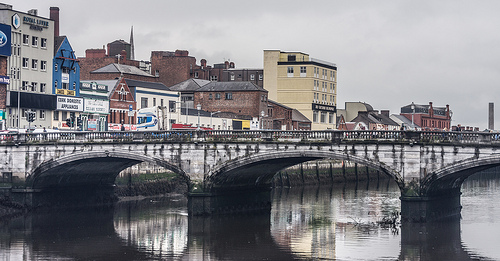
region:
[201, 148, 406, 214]
a stone archway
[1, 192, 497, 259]
part of a reflective river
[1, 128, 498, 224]
a long stone white dirty bridge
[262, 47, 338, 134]
a tall building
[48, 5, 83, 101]
a blue building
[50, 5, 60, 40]
a red brick fire chimney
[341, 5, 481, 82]
a patch of grey sky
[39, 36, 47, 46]
a single window of a building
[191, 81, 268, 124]
a break building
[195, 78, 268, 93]
a black pointed roof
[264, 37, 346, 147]
a tall multi story building.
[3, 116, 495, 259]
A bridge spanning a river.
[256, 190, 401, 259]
A reflection of a city.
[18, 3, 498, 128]
A hazy cloud filled sky.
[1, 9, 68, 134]
a tall white building.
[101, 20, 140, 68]
A building in a city.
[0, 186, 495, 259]
A large body of water.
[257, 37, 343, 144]
a multi story building.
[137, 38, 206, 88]
a small red building.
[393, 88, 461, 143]
a two story building.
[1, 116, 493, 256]
a bridge over a river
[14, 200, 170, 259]
reflection of bridge on the water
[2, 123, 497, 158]
bridge is fenced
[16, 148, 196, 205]
arch on bridge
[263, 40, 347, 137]
a yellow building in front a river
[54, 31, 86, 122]
a blue building in front a river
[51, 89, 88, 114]
a sign in front a building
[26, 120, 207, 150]
people crossing the bridge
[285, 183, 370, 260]
reflection of building on the water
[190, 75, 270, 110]
black roof of building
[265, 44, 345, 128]
a brown building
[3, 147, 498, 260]
water under a bridge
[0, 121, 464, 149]
bridge with cars driving on it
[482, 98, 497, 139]
smoke stack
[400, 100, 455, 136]
red house up on hill with many windows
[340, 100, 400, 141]
house with two chimneys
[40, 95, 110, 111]
two advertising signs hanging on poles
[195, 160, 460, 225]
arch of a bridge with water below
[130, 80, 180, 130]
building with many windows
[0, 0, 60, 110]
white business building with windows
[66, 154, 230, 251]
water under the bridge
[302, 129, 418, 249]
water under the bridge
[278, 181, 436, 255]
water under the bridge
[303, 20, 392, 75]
the sky is overcast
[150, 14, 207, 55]
the sky is overcast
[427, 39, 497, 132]
the sky is overcast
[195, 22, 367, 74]
the sky is overcast